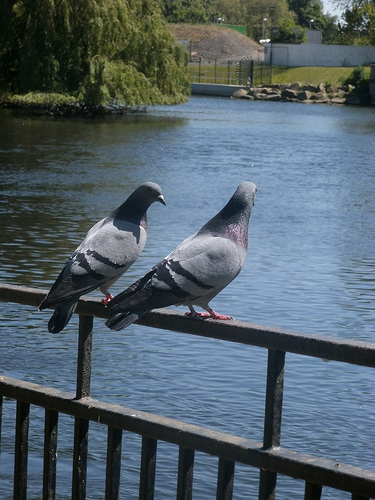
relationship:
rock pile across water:
[226, 78, 354, 107] [4, 93, 372, 497]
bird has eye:
[38, 182, 166, 337] [143, 182, 152, 203]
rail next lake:
[0, 275, 375, 500] [6, 80, 371, 315]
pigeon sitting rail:
[104, 180, 257, 331] [0, 275, 375, 500]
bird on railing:
[38, 182, 166, 337] [0, 311, 373, 499]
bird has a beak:
[38, 182, 166, 337] [158, 195, 168, 210]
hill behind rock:
[184, 60, 373, 87] [313, 91, 328, 99]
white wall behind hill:
[261, 42, 373, 66] [180, 63, 373, 105]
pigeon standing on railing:
[104, 180, 257, 331] [1, 281, 374, 372]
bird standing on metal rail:
[38, 182, 166, 337] [3, 275, 373, 404]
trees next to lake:
[0, 0, 194, 108] [1, 97, 374, 495]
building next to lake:
[263, 34, 373, 67] [1, 97, 374, 495]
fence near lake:
[156, 59, 283, 91] [1, 97, 374, 495]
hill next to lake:
[184, 60, 373, 87] [23, 85, 359, 424]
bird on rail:
[38, 182, 166, 337] [0, 275, 375, 500]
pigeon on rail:
[93, 172, 261, 332] [0, 275, 375, 500]